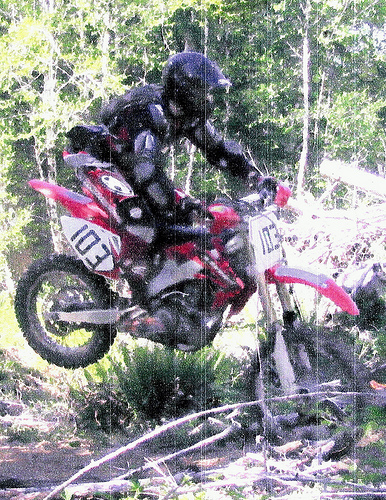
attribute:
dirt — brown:
[0, 426, 242, 486]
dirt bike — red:
[49, 173, 299, 347]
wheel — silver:
[248, 322, 371, 461]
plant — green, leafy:
[87, 330, 240, 414]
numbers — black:
[235, 212, 304, 273]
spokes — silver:
[30, 278, 101, 349]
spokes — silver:
[311, 350, 337, 392]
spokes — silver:
[38, 277, 65, 294]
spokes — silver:
[266, 349, 348, 436]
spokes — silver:
[38, 280, 85, 341]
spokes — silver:
[262, 356, 350, 444]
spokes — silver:
[39, 274, 81, 332]